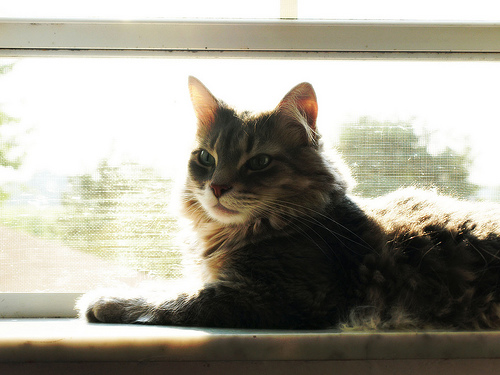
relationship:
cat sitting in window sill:
[74, 74, 499, 332] [0, 316, 498, 365]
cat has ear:
[74, 74, 499, 332] [273, 80, 319, 129]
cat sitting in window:
[74, 74, 499, 332] [0, 0, 499, 320]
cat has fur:
[74, 74, 499, 332] [76, 74, 500, 330]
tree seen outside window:
[334, 113, 488, 202] [0, 0, 499, 320]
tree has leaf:
[334, 113, 488, 202] [464, 158, 474, 167]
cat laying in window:
[74, 74, 499, 332] [0, 0, 499, 320]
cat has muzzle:
[74, 74, 499, 332] [194, 181, 261, 224]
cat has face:
[74, 74, 499, 332] [188, 144, 281, 224]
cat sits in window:
[74, 74, 499, 332] [0, 0, 499, 320]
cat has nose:
[74, 74, 499, 332] [209, 182, 232, 198]